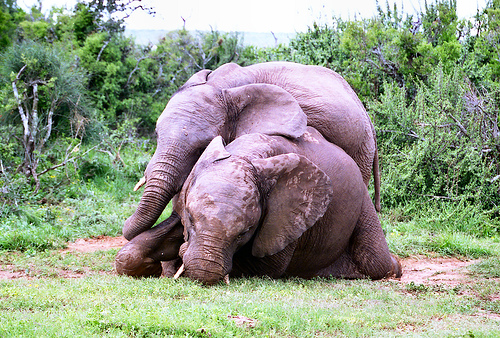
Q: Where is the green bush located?
A: Next to the elephants.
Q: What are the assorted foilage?
A: Green trees and bushes.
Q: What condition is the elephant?
A: Muddy.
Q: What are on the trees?
A: Leafy.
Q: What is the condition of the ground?
A: Muddy and grassy.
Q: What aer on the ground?
A: The two elephants.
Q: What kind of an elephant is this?
A: A very large elephant.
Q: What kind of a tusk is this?
A: A white tusk.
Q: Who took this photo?
A: Jackson Mingus.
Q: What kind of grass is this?
A: Green grass.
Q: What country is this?
A: South African.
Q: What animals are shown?
A: Elephants.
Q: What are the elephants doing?
A: Wrestling.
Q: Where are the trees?
A: Behind the elephants.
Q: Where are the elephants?
A: In front of the tree.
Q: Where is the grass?
A: Under the elephants.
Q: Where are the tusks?
A: On the elephants.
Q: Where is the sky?
A: Above the trees.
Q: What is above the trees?
A: The sky.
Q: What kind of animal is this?
A: Elephant.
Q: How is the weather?
A: Sunny.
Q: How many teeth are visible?
A: Three.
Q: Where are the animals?
A: On top of each other.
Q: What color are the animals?
A: Gray.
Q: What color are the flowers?
A: Purple.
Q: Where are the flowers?
A: Behind the elephants.